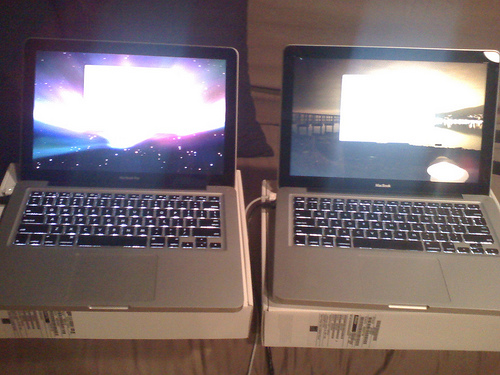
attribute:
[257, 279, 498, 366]
box — cardboard, white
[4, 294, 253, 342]
box — white, cardboard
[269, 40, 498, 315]
computer — grey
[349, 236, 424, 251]
space bar — long, rectangular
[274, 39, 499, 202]
monitor — on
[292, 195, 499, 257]
keyboard — black, illuminated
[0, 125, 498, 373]
table — wooden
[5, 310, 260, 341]
box — white, cardboard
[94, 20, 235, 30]
pillow — dark colored, propped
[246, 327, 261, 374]
cord — white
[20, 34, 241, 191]
laptop screen — illuminated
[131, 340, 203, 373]
paneling — wood